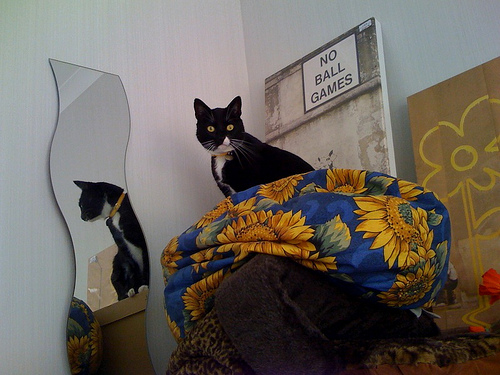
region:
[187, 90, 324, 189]
A black and white cat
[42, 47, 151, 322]
A mirror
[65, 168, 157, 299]
Reflection of cat in the mirror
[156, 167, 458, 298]
A blanket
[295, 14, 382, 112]
A board with a writing no ball game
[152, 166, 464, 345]
Blue and yellow color blanket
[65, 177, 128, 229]
A belt on cats's neck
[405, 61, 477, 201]
A board with a drawing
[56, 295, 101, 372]
Reflection of the blanket in the mirror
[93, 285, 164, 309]
cat's leg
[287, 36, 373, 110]
NO BALL GAMES written on the sign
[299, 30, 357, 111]
sign is black and white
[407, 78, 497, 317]
yellow flower on the board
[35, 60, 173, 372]
mirror against the wall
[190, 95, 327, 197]
cat on top of the beanbag chair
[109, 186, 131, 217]
cat's collar is yellow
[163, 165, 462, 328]
beanbag chair has daisies all over it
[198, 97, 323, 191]
cat is black with a little white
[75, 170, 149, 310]
cat's reflection in the mirror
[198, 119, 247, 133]
cat has yellow eyes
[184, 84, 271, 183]
this is a cat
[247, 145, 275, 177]
the cat is black in color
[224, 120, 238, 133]
the eye is yellow in color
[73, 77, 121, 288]
this is a mirror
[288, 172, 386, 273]
this is a duvee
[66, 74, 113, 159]
the mirror is clear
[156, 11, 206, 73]
the wall is white in color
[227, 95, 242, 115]
this is the ear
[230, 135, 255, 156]
these are the whiskers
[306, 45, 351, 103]
it is written no ball games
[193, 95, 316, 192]
black and white tuxedo cat sitting on top of a shelf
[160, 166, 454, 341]
a blue and gold pillow with sunflower design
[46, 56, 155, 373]
a curvy shaped long mirror hanging on a wall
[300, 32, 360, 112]
a sign with the words "no ball games" found on a canvas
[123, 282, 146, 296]
two front white paws on an adult cat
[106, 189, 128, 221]
yellow collar around the neck of a black and white cat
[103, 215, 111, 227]
identification tag on a yellow collar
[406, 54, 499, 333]
a painting on a large canvas that include a yellow flower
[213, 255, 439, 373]
dark brown wedge pillow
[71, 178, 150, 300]
mirror reflection of a black and white adult feline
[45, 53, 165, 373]
A curvy mirror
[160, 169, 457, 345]
A blanket with flowers on it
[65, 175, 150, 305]
The reflection of a cat in a mirror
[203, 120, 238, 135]
Green cat eyes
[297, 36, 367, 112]
A small white sign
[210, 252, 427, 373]
A fluffy black blanket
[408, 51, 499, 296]
Piece of cardboard with a flower drawn on it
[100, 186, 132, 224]
An orange cat collar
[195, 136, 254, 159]
White cat whiskers